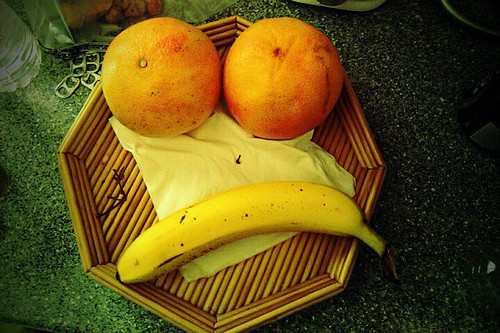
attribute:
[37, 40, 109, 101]
tabs — silver, small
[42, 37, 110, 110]
tabs — steel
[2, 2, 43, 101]
bottle — in corner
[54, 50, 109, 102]
tabs — steel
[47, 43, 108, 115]
tabs — soda can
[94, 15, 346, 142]
oranges — large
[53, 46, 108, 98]
tabs — from soda cans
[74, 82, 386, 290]
napkin — in basket, white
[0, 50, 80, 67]
glass — empty, drinking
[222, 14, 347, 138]
orange — round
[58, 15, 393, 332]
basket — wicker and brown, shaped like an octagon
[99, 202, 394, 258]
banana — ripe, in basket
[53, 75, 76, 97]
pull tab — one, silver soda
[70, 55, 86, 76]
pull tab — one, silver soda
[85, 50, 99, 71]
pull tab — one, silver soda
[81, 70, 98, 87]
pull tab — one, silver soda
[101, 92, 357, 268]
napkin — crumpled, white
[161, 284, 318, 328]
plate — wooden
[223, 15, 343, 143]
grapefruit — fresh, unpeeled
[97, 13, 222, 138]
grapefruit — fresh, unpeeled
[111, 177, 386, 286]
banana — very ripe, one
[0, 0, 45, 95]
bottle — plastic, of water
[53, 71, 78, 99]
pull tab — a pile, soda can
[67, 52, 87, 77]
pull tab — a pile, soda can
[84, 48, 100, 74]
pull tab — a pile, soda can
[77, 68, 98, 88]
pull tab — a pile, soda can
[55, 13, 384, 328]
plate — wooden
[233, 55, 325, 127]
oranges — round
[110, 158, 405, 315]
banana — yellow